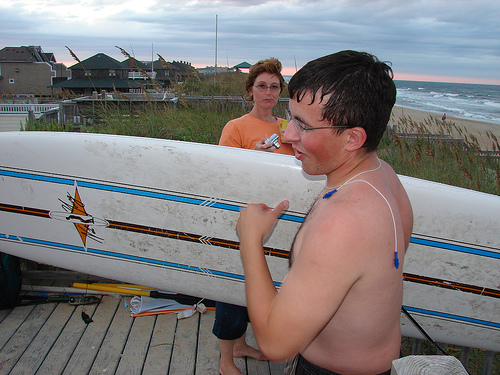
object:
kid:
[232, 47, 416, 375]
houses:
[0, 44, 73, 105]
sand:
[386, 104, 500, 154]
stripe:
[0, 163, 499, 262]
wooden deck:
[0, 114, 44, 134]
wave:
[393, 85, 499, 125]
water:
[393, 77, 500, 128]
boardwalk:
[0, 294, 292, 374]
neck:
[324, 151, 379, 192]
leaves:
[139, 107, 155, 119]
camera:
[263, 132, 282, 150]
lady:
[212, 56, 294, 375]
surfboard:
[1, 125, 500, 356]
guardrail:
[0, 102, 59, 115]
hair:
[285, 48, 397, 154]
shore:
[385, 103, 500, 153]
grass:
[17, 70, 255, 146]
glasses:
[251, 80, 283, 93]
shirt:
[217, 112, 295, 156]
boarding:
[111, 312, 159, 374]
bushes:
[373, 107, 498, 196]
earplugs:
[321, 154, 401, 269]